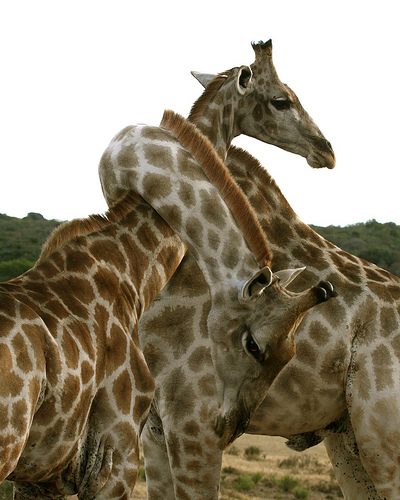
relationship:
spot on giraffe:
[60, 328, 80, 370] [2, 49, 338, 475]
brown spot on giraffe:
[52, 263, 173, 325] [192, 70, 398, 307]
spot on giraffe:
[136, 221, 160, 253] [2, 49, 338, 475]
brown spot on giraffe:
[91, 234, 129, 274] [2, 49, 338, 475]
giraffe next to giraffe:
[98, 109, 398, 500] [185, 27, 337, 176]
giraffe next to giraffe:
[2, 49, 338, 475] [98, 113, 398, 494]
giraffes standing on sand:
[0, 35, 399, 497] [223, 445, 338, 498]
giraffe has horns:
[98, 113, 398, 494] [276, 277, 341, 327]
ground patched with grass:
[236, 463, 281, 479] [275, 474, 315, 495]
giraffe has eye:
[98, 113, 398, 494] [247, 333, 259, 355]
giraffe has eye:
[2, 49, 338, 475] [272, 97, 290, 110]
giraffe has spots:
[2, 49, 338, 475] [4, 283, 144, 439]